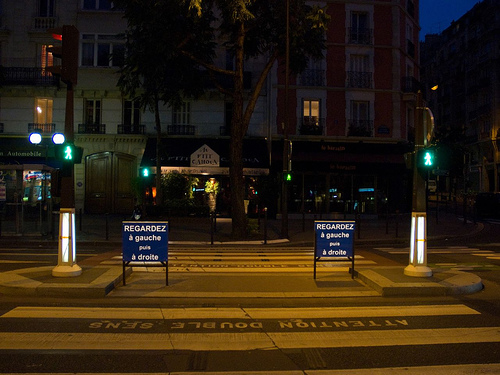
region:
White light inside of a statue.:
[410, 239, 455, 283]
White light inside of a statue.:
[202, 141, 262, 206]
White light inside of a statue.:
[66, 47, 123, 129]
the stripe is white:
[259, 325, 422, 350]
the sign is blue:
[303, 217, 366, 286]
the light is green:
[281, 167, 303, 188]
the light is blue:
[418, 149, 440, 171]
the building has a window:
[28, 93, 64, 134]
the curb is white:
[378, 282, 429, 297]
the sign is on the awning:
[179, 137, 225, 176]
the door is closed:
[76, 147, 137, 215]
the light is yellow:
[192, 174, 220, 215]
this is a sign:
[120, 216, 177, 288]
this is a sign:
[307, 213, 365, 282]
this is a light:
[30, 125, 39, 146]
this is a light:
[414, 142, 440, 167]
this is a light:
[139, 164, 155, 176]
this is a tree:
[187, 2, 274, 239]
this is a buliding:
[0, 0, 413, 222]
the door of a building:
[84, 151, 134, 232]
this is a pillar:
[51, 204, 93, 264]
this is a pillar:
[402, 191, 447, 281]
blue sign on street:
[111, 216, 181, 289]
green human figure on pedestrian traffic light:
[411, 143, 439, 175]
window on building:
[293, 93, 326, 135]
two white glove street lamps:
[25, 126, 69, 152]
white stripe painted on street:
[5, 297, 485, 322]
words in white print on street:
[77, 314, 421, 333]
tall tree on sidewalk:
[119, 21, 330, 238]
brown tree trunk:
[212, 31, 271, 238]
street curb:
[9, 232, 291, 252]